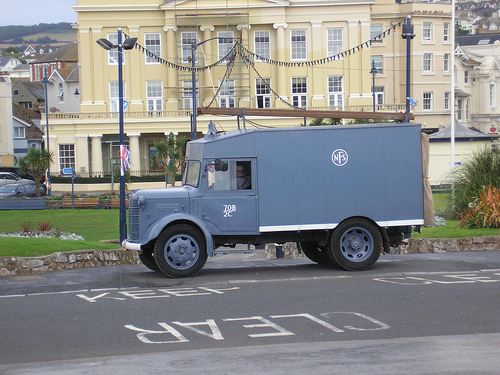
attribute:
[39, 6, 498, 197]
building — large, yellow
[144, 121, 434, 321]
truck — blue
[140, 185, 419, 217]
truck — blue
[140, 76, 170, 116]
window — white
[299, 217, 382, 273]
wheels — back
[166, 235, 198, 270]
rim — blue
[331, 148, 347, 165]
logo — white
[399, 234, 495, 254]
step — stone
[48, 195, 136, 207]
bench — brown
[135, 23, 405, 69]
flags — rope 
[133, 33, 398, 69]
flags — rope 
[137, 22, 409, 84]
flags — rope 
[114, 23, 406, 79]
flags — rope 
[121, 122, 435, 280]
truck — light blue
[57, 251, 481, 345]
pavement — words 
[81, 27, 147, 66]
light — blue street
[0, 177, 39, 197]
car — grey 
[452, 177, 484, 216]
bush — orange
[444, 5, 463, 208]
pole — tall white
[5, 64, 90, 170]
house —  dark grey 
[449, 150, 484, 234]
tree —  interesting spiky green 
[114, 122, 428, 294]
truck — Slate blue armored 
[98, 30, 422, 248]
poles — Three metal blue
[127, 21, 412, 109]
lights — Four hanging strings 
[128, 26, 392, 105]
lights — Four hanging strings 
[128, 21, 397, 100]
lights — Four hanging strings 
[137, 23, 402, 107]
lights — Four hanging strings 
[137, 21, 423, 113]
lights — Four hanging strings 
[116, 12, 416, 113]
lights — Four hanging strings 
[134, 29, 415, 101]
lights — Four hanging strings 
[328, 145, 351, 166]
letters — white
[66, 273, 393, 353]
words — clear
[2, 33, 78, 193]
houses — distant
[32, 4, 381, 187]
building — large